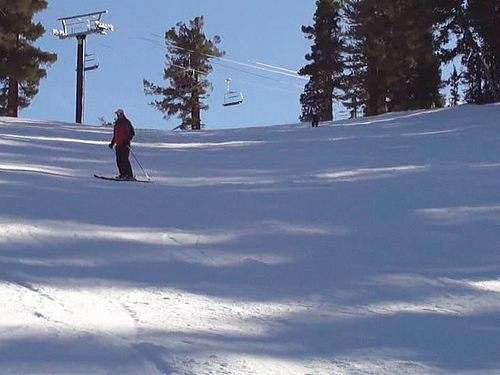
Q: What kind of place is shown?
A: It is a field.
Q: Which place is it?
A: It is a field.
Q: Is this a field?
A: Yes, it is a field.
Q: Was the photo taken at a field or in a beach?
A: It was taken at a field.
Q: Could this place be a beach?
A: No, it is a field.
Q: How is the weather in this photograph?
A: It is sunny.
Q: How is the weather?
A: It is sunny.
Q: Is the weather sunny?
A: Yes, it is sunny.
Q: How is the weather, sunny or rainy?
A: It is sunny.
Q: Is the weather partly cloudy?
A: No, it is sunny.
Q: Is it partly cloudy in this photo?
A: No, it is sunny.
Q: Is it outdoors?
A: Yes, it is outdoors.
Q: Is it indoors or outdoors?
A: It is outdoors.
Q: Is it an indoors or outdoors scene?
A: It is outdoors.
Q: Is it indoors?
A: No, it is outdoors.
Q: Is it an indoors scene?
A: No, it is outdoors.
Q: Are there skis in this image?
A: Yes, there are skis.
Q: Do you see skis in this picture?
A: Yes, there are skis.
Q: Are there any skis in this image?
A: Yes, there are skis.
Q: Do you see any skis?
A: Yes, there are skis.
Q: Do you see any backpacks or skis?
A: Yes, there are skis.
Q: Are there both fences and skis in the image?
A: No, there are skis but no fences.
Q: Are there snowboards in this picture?
A: No, there are no snowboards.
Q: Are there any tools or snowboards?
A: No, there are no snowboards or tools.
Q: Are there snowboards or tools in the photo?
A: No, there are no snowboards or tools.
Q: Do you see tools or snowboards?
A: No, there are no snowboards or tools.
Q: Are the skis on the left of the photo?
A: Yes, the skis are on the left of the image.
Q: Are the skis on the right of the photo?
A: No, the skis are on the left of the image.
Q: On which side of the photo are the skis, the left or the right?
A: The skis are on the left of the image.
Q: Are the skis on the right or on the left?
A: The skis are on the left of the image.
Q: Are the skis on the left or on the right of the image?
A: The skis are on the left of the image.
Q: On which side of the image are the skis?
A: The skis are on the left of the image.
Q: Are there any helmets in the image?
A: No, there are no helmets.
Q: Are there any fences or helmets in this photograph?
A: No, there are no helmets or fences.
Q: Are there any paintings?
A: No, there are no paintings.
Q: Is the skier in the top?
A: Yes, the skier is in the top of the image.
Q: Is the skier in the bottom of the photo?
A: No, the skier is in the top of the image.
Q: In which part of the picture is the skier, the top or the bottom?
A: The skier is in the top of the image.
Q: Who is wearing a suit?
A: The skier is wearing a suit.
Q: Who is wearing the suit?
A: The skier is wearing a suit.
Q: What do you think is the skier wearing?
A: The skier is wearing a suit.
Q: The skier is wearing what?
A: The skier is wearing a suit.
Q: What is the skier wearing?
A: The skier is wearing a suit.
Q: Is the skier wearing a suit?
A: Yes, the skier is wearing a suit.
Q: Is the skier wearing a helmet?
A: No, the skier is wearing a suit.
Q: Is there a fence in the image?
A: No, there are no fences.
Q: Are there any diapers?
A: No, there are no diapers.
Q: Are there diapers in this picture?
A: No, there are no diapers.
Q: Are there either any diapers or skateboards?
A: No, there are no diapers or skateboards.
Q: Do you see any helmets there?
A: No, there are no helmets.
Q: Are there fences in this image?
A: No, there are no fences.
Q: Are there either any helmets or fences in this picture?
A: No, there are no fences or helmets.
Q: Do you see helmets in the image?
A: No, there are no helmets.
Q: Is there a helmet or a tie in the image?
A: No, there are no helmets or ties.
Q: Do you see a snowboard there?
A: No, there are no snowboards.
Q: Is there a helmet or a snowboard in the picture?
A: No, there are no snowboards or helmets.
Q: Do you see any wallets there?
A: No, there are no wallets.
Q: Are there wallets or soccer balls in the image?
A: No, there are no wallets or soccer balls.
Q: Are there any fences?
A: No, there are no fences.